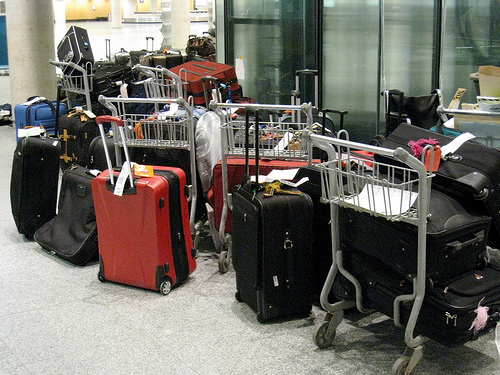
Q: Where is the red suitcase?
A: On the floor.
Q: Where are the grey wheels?
A: On cart.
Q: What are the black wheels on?
A: Suitcase.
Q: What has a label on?
A: Red suitcase.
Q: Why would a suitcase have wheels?
A: To roll.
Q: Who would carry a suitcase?
A: A woman.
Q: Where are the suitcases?
A: Airport.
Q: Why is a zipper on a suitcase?
A: To open and close.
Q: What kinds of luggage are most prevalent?
A: Red and black.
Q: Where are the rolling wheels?
A: On the luggage carts.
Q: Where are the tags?
A: On the suitcases.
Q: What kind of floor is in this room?
A: Gray and white tile.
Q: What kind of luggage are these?
A: Rolling.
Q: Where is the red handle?
A: On the red luggage in front.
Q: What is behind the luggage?
A: Glass windows.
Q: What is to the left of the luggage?
A: A round pillar.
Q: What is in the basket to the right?
A: A white sheet of paper.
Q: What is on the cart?
A: Suitcase.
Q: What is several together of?
A: Suitcases.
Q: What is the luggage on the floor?
A: The selection.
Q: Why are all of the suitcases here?
A: They are waiting to be picked up.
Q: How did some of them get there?
A: They were on a cart.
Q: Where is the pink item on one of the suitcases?
A: On a black suitcase with red tag.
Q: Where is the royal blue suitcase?
A: To the left of all of the others.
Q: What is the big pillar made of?
A: Concrete.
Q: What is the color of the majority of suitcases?
A: Black.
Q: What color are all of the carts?
A: Gray.